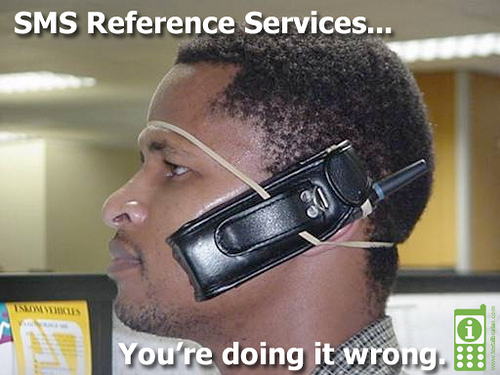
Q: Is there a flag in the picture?
A: No, there are no flags.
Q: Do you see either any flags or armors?
A: No, there are no flags or armors.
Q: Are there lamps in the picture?
A: No, there are no lamps.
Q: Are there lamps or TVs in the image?
A: No, there are no lamps or tvs.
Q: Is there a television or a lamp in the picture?
A: No, there are no lamps or televisions.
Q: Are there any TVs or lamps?
A: No, there are no lamps or tvs.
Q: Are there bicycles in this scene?
A: No, there are no bicycles.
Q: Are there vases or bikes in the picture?
A: No, there are no bikes or vases.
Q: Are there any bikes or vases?
A: No, there are no bikes or vases.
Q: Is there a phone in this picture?
A: Yes, there is a phone.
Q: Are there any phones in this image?
A: Yes, there is a phone.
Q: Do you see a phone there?
A: Yes, there is a phone.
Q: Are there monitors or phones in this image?
A: Yes, there is a phone.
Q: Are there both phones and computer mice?
A: No, there is a phone but no computer mice.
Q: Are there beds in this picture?
A: No, there are no beds.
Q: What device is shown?
A: The device is a phone.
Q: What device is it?
A: The device is a phone.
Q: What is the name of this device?
A: This is a phone.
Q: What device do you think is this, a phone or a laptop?
A: This is a phone.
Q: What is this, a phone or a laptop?
A: This is a phone.